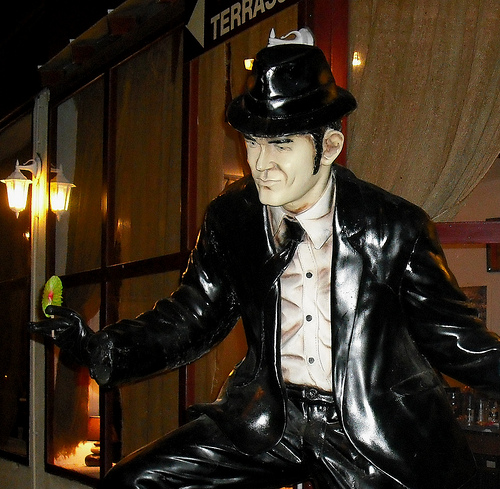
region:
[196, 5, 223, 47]
a letter on the sign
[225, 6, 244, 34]
a letter on the sign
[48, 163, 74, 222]
this is a lamp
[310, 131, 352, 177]
an ear of a statue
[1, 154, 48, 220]
Light fixture on the wall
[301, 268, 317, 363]
Black buttons on statue's shirt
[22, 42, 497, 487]
Statue of man in black hat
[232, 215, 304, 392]
Black tie around statue's neck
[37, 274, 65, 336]
Small decoration held in statue's hand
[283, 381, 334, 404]
Black belt around statue's waist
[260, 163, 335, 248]
White shirt collar around statue's neck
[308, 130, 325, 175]
Black sideburn on side of statue's face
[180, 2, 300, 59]
Sign with arrow on the wall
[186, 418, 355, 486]
the pants are black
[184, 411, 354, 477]
the pants are shiny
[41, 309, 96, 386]
the glove is black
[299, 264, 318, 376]
the buttons are black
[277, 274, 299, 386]
wrinkles in the shirt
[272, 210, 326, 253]
tie under the collar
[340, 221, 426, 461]
the jacket is shiny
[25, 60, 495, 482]
this is a statue of a man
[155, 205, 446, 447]
the coat is black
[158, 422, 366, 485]
the pants are black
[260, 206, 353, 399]
the shirt is tan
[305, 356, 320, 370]
this is a button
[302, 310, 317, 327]
this is a button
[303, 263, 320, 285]
this is a button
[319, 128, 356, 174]
this is an ear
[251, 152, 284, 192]
this is a nose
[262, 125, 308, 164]
this is an eye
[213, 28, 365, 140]
statue with a black hair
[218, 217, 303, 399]
statue with a black tie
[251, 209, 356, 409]
statue wearing a white shirt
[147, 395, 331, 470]
statue wearing black pants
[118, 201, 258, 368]
statue wearing a black jacket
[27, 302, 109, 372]
statue wearing black gloves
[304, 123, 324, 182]
statue with black hair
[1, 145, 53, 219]
statue on the fall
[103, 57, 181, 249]
curtain in the window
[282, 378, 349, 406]
belt on a statue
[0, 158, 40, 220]
light on the side of the building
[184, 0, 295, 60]
a black and white sign on the top of the building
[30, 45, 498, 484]
statue of a man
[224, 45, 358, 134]
shiny black hat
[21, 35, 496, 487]
man's statue wearing hat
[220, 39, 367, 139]
black hat on man's statue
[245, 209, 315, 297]
black tie on statue of man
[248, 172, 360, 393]
white shirt on man's statue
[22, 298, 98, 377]
black glove on statue's hand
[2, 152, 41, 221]
electric light wall sconce.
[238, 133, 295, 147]
black eyebrows on man's statue